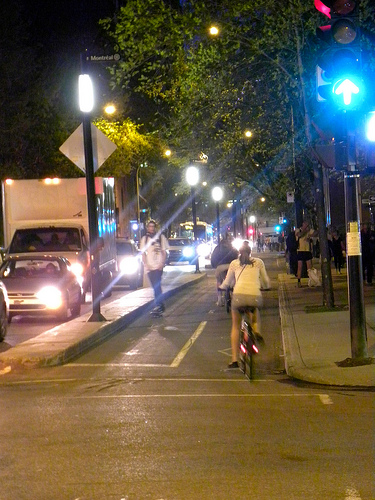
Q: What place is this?
A: It is a road.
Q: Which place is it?
A: It is a road.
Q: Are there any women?
A: Yes, there is a woman.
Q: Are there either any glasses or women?
A: Yes, there is a woman.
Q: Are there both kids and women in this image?
A: No, there is a woman but no children.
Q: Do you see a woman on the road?
A: Yes, there is a woman on the road.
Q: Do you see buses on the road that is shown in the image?
A: No, there is a woman on the road.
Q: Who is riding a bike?
A: The woman is riding a bike.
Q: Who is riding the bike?
A: The woman is riding a bike.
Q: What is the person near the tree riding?
A: The woman is riding a bike.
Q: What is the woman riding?
A: The woman is riding a bike.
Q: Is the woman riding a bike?
A: Yes, the woman is riding a bike.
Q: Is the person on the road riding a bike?
A: Yes, the woman is riding a bike.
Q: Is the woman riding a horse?
A: No, the woman is riding a bike.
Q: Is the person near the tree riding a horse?
A: No, the woman is riding a bike.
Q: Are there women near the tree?
A: Yes, there is a woman near the tree.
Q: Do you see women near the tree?
A: Yes, there is a woman near the tree.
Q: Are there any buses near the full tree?
A: No, there is a woman near the tree.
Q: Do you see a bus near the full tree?
A: No, there is a woman near the tree.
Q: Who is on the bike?
A: The woman is on the bike.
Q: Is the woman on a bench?
A: No, the woman is on the bike.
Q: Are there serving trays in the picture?
A: No, there are no serving trays.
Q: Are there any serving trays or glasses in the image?
A: No, there are no serving trays or glasses.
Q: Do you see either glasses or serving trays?
A: No, there are no serving trays or glasses.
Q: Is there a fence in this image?
A: No, there are no fences.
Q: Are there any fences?
A: No, there are no fences.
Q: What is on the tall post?
A: The sign is on the post.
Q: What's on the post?
A: The sign is on the post.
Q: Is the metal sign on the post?
A: Yes, the sign is on the post.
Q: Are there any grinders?
A: No, there are no grinders.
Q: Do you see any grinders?
A: No, there are no grinders.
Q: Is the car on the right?
A: No, the car is on the left of the image.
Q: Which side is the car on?
A: The car is on the left of the image.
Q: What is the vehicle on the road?
A: The vehicle is a car.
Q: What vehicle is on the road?
A: The vehicle is a car.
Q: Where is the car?
A: The car is on the road.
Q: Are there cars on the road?
A: Yes, there is a car on the road.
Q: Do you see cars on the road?
A: Yes, there is a car on the road.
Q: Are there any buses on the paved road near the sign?
A: No, there is a car on the road.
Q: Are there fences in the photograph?
A: No, there are no fences.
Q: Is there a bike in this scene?
A: Yes, there is a bike.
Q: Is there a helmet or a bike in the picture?
A: Yes, there is a bike.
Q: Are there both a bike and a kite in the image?
A: No, there is a bike but no kites.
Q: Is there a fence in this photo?
A: No, there are no fences.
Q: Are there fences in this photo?
A: No, there are no fences.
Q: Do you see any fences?
A: No, there are no fences.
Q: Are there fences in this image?
A: No, there are no fences.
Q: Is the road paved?
A: Yes, the road is paved.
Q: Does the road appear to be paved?
A: Yes, the road is paved.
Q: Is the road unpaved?
A: No, the road is paved.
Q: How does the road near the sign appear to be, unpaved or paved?
A: The road is paved.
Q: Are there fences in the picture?
A: No, there are no fences.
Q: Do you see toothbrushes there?
A: No, there are no toothbrushes.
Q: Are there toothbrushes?
A: No, there are no toothbrushes.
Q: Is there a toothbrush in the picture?
A: No, there are no toothbrushes.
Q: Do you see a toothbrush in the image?
A: No, there are no toothbrushes.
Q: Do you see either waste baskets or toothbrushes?
A: No, there are no toothbrushes or waste baskets.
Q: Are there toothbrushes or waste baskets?
A: No, there are no toothbrushes or waste baskets.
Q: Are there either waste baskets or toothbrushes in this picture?
A: No, there are no toothbrushes or waste baskets.